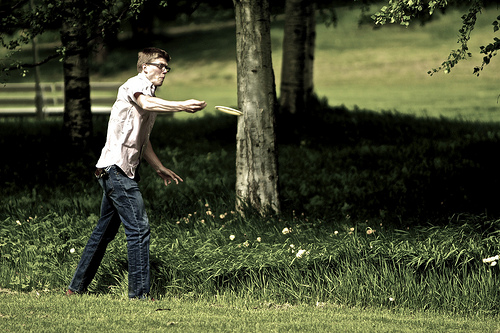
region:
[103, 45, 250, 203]
man throwing frisbee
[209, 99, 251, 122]
yellow frisbee in the air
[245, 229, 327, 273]
white flowers in the grass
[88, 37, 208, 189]
man wearing black glasses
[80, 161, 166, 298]
man wearing blue jeans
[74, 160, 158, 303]
long blue jean pants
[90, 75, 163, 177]
white button up shirt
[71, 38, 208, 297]
man standing on grass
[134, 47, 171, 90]
man with short brown hair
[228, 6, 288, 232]
tree trunk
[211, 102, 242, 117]
off-white frisbee being thrown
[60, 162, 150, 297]
acid washed dark blue jeans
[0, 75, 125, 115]
white picket fence in the background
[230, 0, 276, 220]
big tree trunk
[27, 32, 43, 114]
small tree trunk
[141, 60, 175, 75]
black glasses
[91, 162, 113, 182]
back pocket flap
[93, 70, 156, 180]
light pink button down shirt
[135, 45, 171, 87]
man's head with a strained face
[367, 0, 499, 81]
leaves in the sunlight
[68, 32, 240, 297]
the man is playing frisbee.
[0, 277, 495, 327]
the grass is green.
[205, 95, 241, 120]
frisbee in the air.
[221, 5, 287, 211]
the tree is brown.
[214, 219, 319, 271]
the flowers are white.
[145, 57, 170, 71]
man is wearing glasses.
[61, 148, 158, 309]
man's pants are blue.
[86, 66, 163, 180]
man's shirt is white.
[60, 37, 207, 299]
one man is visible.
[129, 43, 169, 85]
man's hair is brown.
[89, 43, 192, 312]
skinny man throwing frisbee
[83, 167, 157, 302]
man wearing dark blue jeans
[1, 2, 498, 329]
big green park with tree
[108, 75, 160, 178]
man wearing short sleeve shirt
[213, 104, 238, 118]
frisbee flying through park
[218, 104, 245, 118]
yellow round frisbee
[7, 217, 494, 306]
thick tall green grass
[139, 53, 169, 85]
man has brown hair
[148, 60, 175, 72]
man wears glasses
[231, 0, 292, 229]
tall tree in middle of park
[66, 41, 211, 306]
a man throwing a frisbee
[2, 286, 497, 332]
cut grass next to a man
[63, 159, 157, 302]
blue jeans on a man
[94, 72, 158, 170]
a white shirt on a man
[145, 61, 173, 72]
glasses on a man's face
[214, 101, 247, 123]
a frisbee in the air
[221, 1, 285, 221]
a light brown tree trunk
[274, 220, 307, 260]
flowers in tall grass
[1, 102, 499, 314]
tall grass under trees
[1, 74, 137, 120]
a white fence